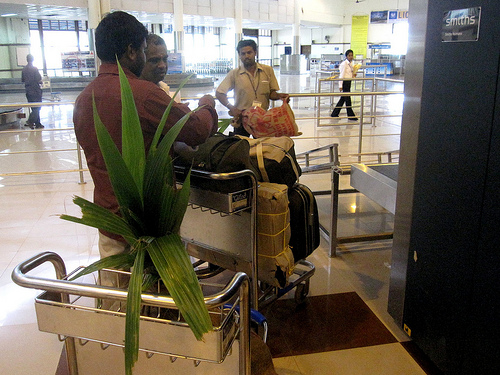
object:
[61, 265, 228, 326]
basket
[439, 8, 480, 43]
sign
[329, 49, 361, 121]
man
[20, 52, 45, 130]
man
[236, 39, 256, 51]
black hair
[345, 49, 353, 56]
black hair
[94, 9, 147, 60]
black hair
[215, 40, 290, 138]
man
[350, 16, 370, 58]
yellow banner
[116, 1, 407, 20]
ceiling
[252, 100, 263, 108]
badge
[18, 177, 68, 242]
floor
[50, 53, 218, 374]
plant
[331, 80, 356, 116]
black pants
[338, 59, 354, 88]
blouse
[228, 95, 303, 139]
bag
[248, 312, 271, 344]
handle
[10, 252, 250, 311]
handle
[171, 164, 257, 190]
handle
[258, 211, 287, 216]
rope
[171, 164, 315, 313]
cart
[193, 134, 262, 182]
bag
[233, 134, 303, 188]
bag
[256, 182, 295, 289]
bag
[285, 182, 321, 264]
bag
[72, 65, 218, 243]
shirt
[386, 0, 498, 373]
wall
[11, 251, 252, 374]
cart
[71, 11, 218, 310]
man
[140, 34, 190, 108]
man